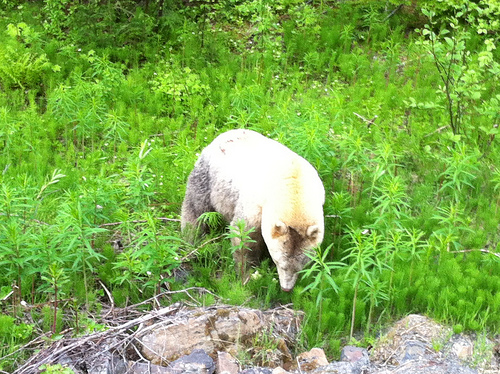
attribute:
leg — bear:
[228, 211, 258, 283]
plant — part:
[418, 23, 487, 174]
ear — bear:
[263, 214, 340, 242]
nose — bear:
[278, 285, 293, 293]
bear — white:
[176, 124, 327, 294]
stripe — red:
[284, 155, 313, 232]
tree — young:
[420, 2, 499, 142]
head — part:
[258, 219, 324, 293]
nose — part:
[282, 272, 302, 296]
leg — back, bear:
[162, 160, 216, 238]